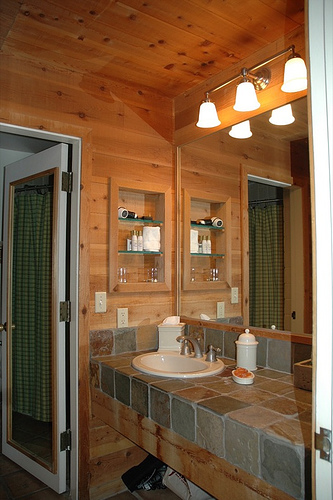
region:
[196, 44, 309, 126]
Overhead sconce in the bathroom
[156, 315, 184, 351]
Tissue holder on the counter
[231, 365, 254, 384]
Soap dish on the counter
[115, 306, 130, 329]
Electrical wall outlet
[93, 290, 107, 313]
Light switch on the wall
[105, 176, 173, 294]
Built in shelves in the bathroom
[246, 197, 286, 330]
Reflection of green curtain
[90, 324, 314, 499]
Rustic tile counter top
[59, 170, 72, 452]
Door hinges on white door fram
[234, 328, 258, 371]
White container on counter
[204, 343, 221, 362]
right handle of the sink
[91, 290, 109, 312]
light switch on the wall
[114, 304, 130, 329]
outlet on the wall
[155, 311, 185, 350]
a square tissue holder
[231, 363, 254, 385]
a soap dish next to the sink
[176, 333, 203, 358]
the faucet of the sink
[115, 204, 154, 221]
a hair dryer on the shelf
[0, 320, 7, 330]
the door knob of the door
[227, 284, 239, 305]
reflection of the light switch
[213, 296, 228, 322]
reflection of the outlet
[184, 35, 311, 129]
three lights hang over the mirror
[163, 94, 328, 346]
a mirror over the sink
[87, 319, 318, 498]
a stone tile counter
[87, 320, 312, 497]
a grey stone counter with natural wood base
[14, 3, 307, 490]
the walls and ceiling are natural wood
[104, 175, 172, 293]
a vanity is built into the wall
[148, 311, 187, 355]
a porcelain tissue holder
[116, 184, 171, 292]
glass shelves are in the medicine cabinet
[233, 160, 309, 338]
a doorway is reflected in the mirror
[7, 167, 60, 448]
a mirror is on the back of the door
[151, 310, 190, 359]
a white tissue dispenser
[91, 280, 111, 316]
a white light switch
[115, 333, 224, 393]
a white bathroom sink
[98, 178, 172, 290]
three shelves in the wall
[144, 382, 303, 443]
a tile bathroom counter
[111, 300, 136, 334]
a white electrical outlet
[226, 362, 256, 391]
a white soap dish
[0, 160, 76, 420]
a door with a mirror hanging on it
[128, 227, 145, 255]
two bottles on a shelf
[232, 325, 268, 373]
a white canister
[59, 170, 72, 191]
Hinge for operating door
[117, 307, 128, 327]
Electrical receptacle in the wall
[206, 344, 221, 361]
Cold water valve bathroom sink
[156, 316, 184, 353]
Tissue dispensers sitting on the bathroom sink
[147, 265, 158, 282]
Drinking glass sitting on a shelf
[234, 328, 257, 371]
Decorative canister sitting on the bathroom sink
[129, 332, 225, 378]
Sink in bathroom countertop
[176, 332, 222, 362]
Water faucet for bathroom sink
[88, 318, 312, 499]
Tiled countertop in bathroom